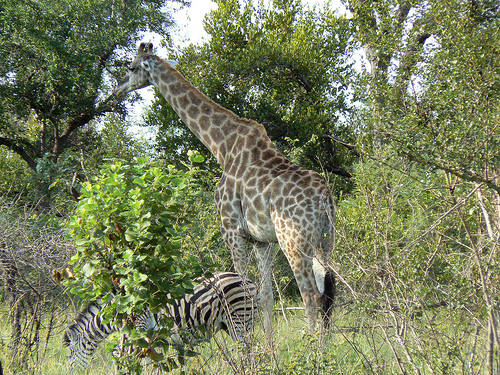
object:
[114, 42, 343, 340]
giraffe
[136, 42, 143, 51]
horns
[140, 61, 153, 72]
ear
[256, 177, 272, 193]
spots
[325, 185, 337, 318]
tail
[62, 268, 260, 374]
zebra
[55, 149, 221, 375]
bush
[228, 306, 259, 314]
stripes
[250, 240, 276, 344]
legs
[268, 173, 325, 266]
hind quarters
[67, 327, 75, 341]
ear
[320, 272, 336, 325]
tail end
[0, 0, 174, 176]
tree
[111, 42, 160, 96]
head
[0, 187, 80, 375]
bush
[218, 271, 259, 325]
backside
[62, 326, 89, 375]
head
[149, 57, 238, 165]
neck